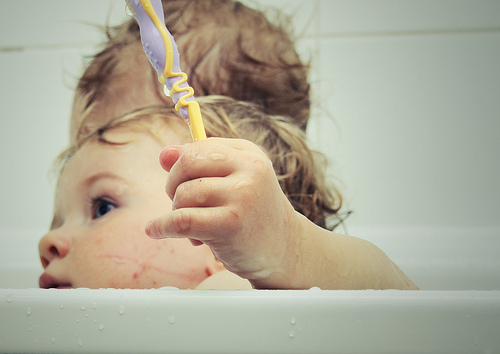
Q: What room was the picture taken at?
A: It was taken at the bathroom.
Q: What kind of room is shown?
A: It is a bathroom.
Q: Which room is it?
A: It is a bathroom.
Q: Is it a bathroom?
A: Yes, it is a bathroom.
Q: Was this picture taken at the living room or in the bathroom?
A: It was taken at the bathroom.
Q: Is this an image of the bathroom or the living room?
A: It is showing the bathroom.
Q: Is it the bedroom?
A: No, it is the bathroom.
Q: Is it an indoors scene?
A: Yes, it is indoors.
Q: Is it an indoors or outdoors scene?
A: It is indoors.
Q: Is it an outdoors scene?
A: No, it is indoors.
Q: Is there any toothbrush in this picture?
A: Yes, there is a toothbrush.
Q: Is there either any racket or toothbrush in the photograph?
A: Yes, there is a toothbrush.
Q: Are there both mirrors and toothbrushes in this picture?
A: No, there is a toothbrush but no mirrors.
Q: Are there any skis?
A: No, there are no skis.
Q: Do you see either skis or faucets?
A: No, there are no skis or faucets.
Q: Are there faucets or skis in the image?
A: No, there are no skis or faucets.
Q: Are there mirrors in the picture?
A: No, there are no mirrors.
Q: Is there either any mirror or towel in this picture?
A: No, there are no mirrors or towels.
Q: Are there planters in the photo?
A: No, there are no planters.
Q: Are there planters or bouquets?
A: No, there are no planters or bouquets.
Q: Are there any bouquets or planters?
A: No, there are no planters or bouquets.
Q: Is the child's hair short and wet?
A: Yes, the hair is short and wet.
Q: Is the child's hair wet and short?
A: Yes, the hair is wet and short.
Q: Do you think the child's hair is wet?
A: Yes, the hair is wet.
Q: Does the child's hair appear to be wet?
A: Yes, the hair is wet.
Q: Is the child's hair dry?
A: No, the hair is wet.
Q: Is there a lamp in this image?
A: No, there are no lamps.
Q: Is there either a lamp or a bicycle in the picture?
A: No, there are no lamps or bicycles.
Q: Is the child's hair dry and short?
A: No, the hair is short but wet.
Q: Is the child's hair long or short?
A: The hair is short.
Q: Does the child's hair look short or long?
A: The hair is short.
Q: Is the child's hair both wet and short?
A: Yes, the hair is wet and short.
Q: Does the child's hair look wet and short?
A: Yes, the hair is wet and short.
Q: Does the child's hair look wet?
A: Yes, the hair is wet.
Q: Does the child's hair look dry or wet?
A: The hair is wet.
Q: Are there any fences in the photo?
A: No, there are no fences.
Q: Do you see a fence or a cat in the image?
A: No, there are no fences or cats.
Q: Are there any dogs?
A: No, there are no dogs.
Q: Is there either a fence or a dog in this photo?
A: No, there are no dogs or fences.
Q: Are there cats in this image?
A: No, there are no cats.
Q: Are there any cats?
A: No, there are no cats.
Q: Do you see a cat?
A: No, there are no cats.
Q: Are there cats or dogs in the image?
A: No, there are no cats or dogs.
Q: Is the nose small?
A: Yes, the nose is small.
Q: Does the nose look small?
A: Yes, the nose is small.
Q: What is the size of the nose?
A: The nose is small.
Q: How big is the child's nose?
A: The nose is small.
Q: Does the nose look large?
A: No, the nose is small.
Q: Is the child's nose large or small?
A: The nose is small.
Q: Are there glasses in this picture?
A: No, there are no glasses.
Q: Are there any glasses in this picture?
A: No, there are no glasses.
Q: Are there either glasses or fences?
A: No, there are no glasses or fences.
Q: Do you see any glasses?
A: No, there are no glasses.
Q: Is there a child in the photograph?
A: Yes, there is a child.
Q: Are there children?
A: Yes, there is a child.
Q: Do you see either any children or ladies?
A: Yes, there is a child.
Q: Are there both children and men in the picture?
A: No, there is a child but no men.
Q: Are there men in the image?
A: No, there are no men.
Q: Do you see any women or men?
A: No, there are no men or women.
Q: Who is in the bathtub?
A: The child is in the bath tub.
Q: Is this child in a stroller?
A: No, the child is in the bathtub.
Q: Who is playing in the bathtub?
A: The child is playing in the tub.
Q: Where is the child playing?
A: The child is playing in the tub.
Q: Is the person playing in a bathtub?
A: Yes, the kid is playing in a bathtub.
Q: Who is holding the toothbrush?
A: The kid is holding the toothbrush.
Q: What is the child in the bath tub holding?
A: The kid is holding the toothbrush.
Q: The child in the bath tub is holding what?
A: The kid is holding the toothbrush.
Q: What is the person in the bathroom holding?
A: The kid is holding the toothbrush.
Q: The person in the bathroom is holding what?
A: The kid is holding the toothbrush.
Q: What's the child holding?
A: The kid is holding the toothbrush.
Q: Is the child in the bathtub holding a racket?
A: No, the kid is holding the toothbrush.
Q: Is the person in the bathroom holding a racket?
A: No, the kid is holding the toothbrush.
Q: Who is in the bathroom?
A: The child is in the bathroom.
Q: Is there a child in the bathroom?
A: Yes, there is a child in the bathroom.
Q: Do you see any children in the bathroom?
A: Yes, there is a child in the bathroom.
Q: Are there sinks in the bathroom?
A: No, there is a child in the bathroom.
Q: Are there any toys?
A: No, there are no toys.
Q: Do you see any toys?
A: No, there are no toys.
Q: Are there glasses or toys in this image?
A: No, there are no toys or glasses.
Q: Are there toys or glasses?
A: No, there are no toys or glasses.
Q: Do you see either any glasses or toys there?
A: No, there are no toys or glasses.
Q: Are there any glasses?
A: No, there are no glasses.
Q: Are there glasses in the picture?
A: No, there are no glasses.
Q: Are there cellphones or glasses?
A: No, there are no glasses or cellphones.